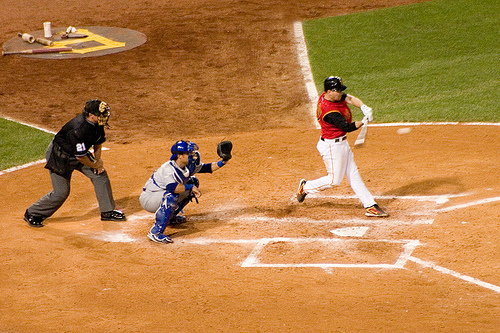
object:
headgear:
[323, 75, 348, 93]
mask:
[98, 102, 112, 128]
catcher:
[136, 138, 235, 244]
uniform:
[137, 162, 214, 234]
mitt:
[217, 141, 234, 161]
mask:
[187, 143, 201, 173]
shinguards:
[152, 194, 180, 236]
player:
[293, 74, 389, 218]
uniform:
[303, 94, 376, 209]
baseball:
[397, 126, 410, 135]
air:
[380, 100, 434, 162]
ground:
[1, 0, 498, 331]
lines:
[404, 254, 500, 294]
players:
[138, 138, 235, 244]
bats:
[1, 44, 73, 56]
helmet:
[170, 140, 200, 161]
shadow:
[382, 174, 462, 205]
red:
[316, 95, 354, 140]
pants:
[305, 137, 378, 206]